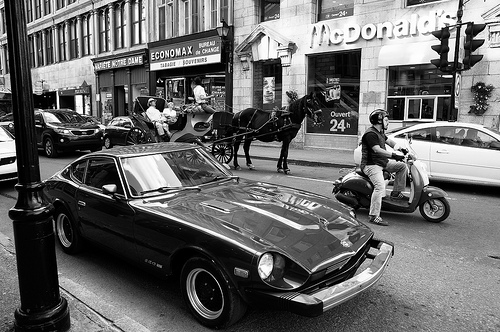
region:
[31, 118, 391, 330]
vintage car is parked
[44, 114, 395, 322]
vintage car is parked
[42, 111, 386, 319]
vintage car is parked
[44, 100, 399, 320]
vintage car is parked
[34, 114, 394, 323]
vintage car is parked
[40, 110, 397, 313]
vintage car is parked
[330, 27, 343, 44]
white letter on building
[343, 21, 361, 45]
white letter on building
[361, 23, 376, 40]
white letter on building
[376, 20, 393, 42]
white letter on building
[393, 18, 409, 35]
white letter on building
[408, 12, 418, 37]
white letter on building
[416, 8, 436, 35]
white letter on building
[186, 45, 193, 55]
white letter on building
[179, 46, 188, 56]
white letter on building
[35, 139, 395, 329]
hotrod car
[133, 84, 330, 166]
horse and buggy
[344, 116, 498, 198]
small white car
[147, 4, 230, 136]
Economax building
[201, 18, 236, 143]
street lamp on road near Mcdonalds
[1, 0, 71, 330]
close streetlamp on street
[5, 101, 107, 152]
black sports truck behind horse and buggy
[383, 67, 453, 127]
building has windows in front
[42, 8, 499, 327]
black and white picture of a town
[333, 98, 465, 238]
man on a scooter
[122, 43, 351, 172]
couple in a horse carriage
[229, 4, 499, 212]
a 24 hour McDonald's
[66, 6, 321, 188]
stores and businesses in a city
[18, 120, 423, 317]
a corvet driving down the road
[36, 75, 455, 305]
vehicles driving down the road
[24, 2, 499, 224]
buildings lining a street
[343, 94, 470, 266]
man wearing a helmet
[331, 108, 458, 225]
man wear in black helmet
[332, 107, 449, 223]
man with helmet riding scooter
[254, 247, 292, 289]
glass headlight on sports car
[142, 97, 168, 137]
man in white shirt riding in buggy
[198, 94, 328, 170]
black horse pulling buggy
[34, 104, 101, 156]
black suv behind horse and buggy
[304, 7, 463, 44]
restuarant sign over window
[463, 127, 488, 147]
person driving white car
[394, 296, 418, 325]
oil stains on the street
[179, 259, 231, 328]
silver and black rims on car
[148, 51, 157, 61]
white letter on building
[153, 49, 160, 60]
white letter on building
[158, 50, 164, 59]
white letter on building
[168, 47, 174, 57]
white letter on building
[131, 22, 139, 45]
window pane on city building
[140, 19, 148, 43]
window pane on city building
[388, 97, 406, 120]
window pane on city building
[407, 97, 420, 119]
window pane on city building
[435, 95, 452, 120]
window pane on city building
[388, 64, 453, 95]
window pane on city building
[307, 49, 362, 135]
window pane on city building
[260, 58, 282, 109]
window pane on city building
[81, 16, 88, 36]
window pane on city building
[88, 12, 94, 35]
window pane on city building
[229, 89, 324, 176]
A black horse pulling a carriage.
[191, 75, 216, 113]
A person looking back who is highest on a carriage.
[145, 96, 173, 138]
Man in a light colored hat in the back of a carriage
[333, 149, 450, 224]
A small scooter on the road.